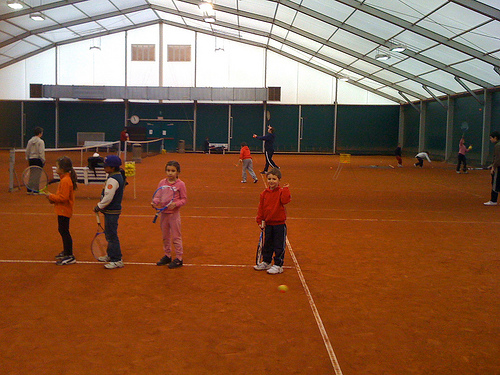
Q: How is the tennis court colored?
A: Orange.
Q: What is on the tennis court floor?
A: White markings.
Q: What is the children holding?
A: Tennis rackets.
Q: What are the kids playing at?
A: Gym.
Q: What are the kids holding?
A: Tennis rackets.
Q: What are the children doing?
A: Playing tennis.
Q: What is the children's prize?
A: A ribbon.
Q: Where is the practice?
A: At an indoor tennis court.